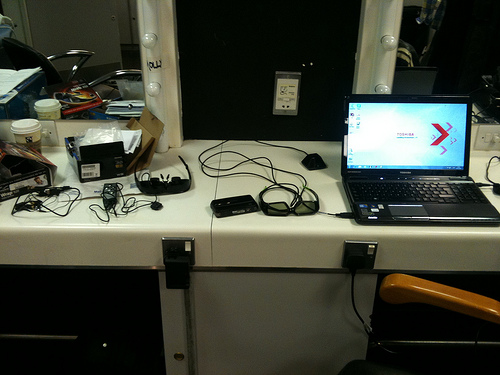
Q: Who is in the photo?
A: Nobody.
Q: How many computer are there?
A: One.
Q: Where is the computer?
A: On a desk.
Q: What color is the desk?
A: White.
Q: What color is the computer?
A: Black.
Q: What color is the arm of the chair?
A: Brown.